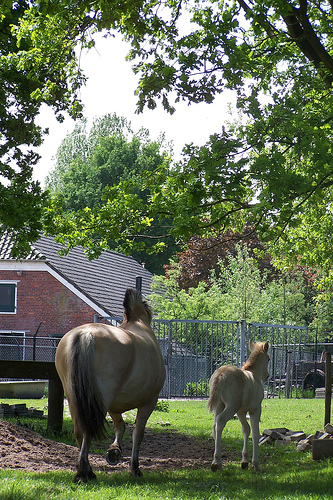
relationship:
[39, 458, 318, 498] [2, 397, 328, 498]
shadow on ground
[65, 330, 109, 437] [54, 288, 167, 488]
tail of animals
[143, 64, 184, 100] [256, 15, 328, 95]
leaves on tree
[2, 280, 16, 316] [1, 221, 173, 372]
window on building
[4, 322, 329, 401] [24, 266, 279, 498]
fence near animals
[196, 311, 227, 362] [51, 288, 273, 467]
fence near horses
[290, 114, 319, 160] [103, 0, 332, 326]
leaves on tree